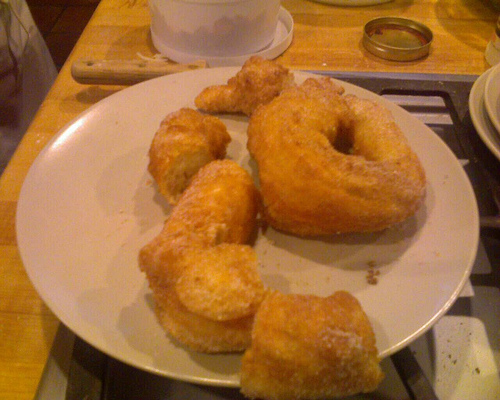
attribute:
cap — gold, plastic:
[347, 17, 453, 65]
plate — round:
[44, 45, 469, 373]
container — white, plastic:
[150, 10, 324, 64]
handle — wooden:
[47, 40, 235, 83]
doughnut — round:
[237, 90, 395, 255]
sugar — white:
[171, 174, 202, 215]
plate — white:
[55, 210, 172, 359]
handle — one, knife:
[62, 51, 195, 73]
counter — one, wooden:
[80, 8, 497, 81]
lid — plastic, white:
[136, 6, 316, 68]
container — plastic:
[134, 3, 297, 60]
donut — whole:
[249, 69, 429, 229]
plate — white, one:
[19, 46, 477, 386]